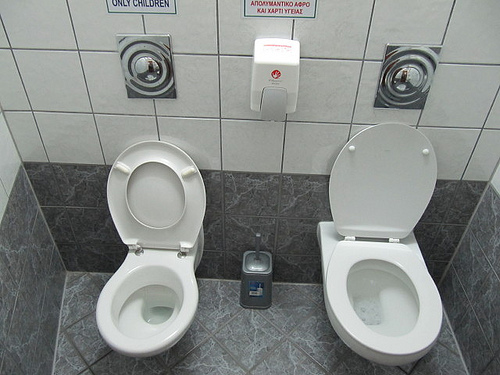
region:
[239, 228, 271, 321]
a grey toilet brush cover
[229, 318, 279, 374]
grey marble flooring tile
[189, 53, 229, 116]
white wall tile in a bathroom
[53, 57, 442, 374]
a pair of toilets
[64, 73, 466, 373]
two toilets side by side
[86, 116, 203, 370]
a toilet for children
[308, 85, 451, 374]
a toilet for adults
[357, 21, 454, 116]
a silver flush button on the wall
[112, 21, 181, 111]
a silver flush button on the wall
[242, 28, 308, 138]
a white and red soap dispenser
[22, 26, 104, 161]
The toilet wall is white.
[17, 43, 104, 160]
The toilet wall is made of tile.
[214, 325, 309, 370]
The bathroom floor is gray.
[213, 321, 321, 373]
The bathroom floor is made of tile.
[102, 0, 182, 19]
The sign on the wall is blue and white.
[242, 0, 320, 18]
The sign on the wall is red and white.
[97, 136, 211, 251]
The toilet lid is white.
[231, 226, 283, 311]
The toilet cleaner is gray.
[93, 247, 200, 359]
The toilet bowl is white.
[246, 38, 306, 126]
The hand wash station is white and red.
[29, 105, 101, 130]
Dark grey grout line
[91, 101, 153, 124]
Dark grey grout line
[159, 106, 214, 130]
Dark grey grout line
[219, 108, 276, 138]
Dark grey grout line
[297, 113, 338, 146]
Dark grey grout line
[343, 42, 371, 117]
Dark grey grout line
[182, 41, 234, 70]
Dark grey grout line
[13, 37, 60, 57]
Dark grey grout line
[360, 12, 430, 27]
Dark grey grout line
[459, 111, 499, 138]
Dark grey grout line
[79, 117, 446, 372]
two white toilets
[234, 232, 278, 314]
gray toilet brush in holder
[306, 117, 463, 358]
white toilet with lid up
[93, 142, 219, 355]
white toilet with lid and seat up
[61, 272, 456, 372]
gray tiles on the floor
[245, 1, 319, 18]
white sign with red lettering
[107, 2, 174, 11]
black lettering on white sign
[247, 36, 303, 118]
white dispenser between two toilets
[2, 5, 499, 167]
white tiles on the wall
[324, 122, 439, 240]
raised lid of white toilet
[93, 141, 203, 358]
toilet is next to toilet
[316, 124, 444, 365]
toilet is next to toilet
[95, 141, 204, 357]
toilet is for children only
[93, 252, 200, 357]
toilet bowl is white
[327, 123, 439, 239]
toilet lid is open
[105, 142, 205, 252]
toilet seat is up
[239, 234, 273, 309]
toilet brush is gray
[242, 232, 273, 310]
toilet bowl is plastic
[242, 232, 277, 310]
toilet bowl is between two toilets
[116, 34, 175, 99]
chrome button behind toilet